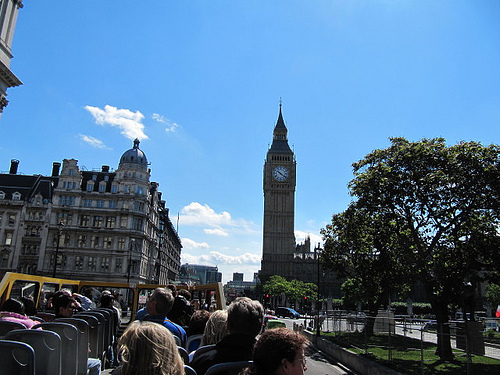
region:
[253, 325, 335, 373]
the head of a man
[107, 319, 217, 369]
the head of a woman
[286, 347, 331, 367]
a person wearing glasses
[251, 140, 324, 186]
a really big clock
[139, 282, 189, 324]
the back of a man head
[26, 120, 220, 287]
a big building in the background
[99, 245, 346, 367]
people walking down the street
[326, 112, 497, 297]
a tree with green leaves on it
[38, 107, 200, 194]
the top of a building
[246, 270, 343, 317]
a street light that is red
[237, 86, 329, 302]
the Big Ben is visble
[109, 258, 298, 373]
tourist in the bus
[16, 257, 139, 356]
tourist in the bus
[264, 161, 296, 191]
Large black and white clock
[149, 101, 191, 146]
Small white cloud in the sky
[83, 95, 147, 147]
Small white cloud in the sky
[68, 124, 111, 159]
Small white cloud in the sky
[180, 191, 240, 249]
Small white cloud in the sky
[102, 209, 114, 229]
Small window of a building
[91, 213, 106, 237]
Small window of a building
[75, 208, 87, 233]
Small window of a building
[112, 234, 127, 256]
Small window of a building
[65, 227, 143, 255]
Small window of a building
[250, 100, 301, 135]
top part of the pillar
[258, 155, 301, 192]
a clock in the tower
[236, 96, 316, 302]
a very long pillar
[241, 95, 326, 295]
a pillar with clock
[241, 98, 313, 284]
a tower with clock on top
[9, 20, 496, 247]
a beautiful view of sky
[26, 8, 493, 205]
a clear view of sky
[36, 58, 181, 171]
a small white cloud in sky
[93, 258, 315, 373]
a group of people standing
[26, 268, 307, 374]
a group of people walking near building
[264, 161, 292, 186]
clock on tall building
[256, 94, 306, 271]
large tower attached to building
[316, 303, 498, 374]
fence closes in grassy area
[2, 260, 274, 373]
tour bus is driving down the road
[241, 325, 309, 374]
woman riding tour bus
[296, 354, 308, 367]
woman on bus wearing glasses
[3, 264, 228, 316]
tourist bus has no ceiling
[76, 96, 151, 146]
very few clouds in sky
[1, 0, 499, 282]
sky is bright and very blue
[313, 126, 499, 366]
large tree in enclosed fence